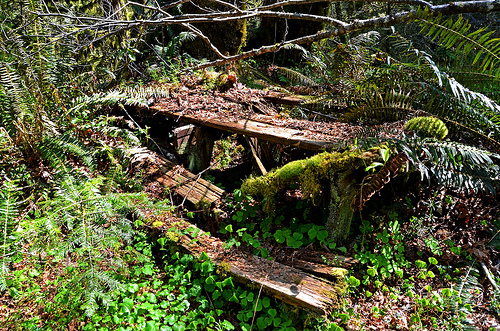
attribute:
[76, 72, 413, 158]
board — wooden, broken, bright, fallen, brown, wood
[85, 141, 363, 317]
board — wooden, wood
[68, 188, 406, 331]
clovers — green, lucky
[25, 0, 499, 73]
branch — dry, brown, bare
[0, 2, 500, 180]
trees — green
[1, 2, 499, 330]
jungle — dirty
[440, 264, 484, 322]
ivy — green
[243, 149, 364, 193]
moss — green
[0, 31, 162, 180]
fern — green, growing, brown, dying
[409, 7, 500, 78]
leaf — green, brown, dry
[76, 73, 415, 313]
table — old, broken, brown, wooden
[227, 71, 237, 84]
flower — orange